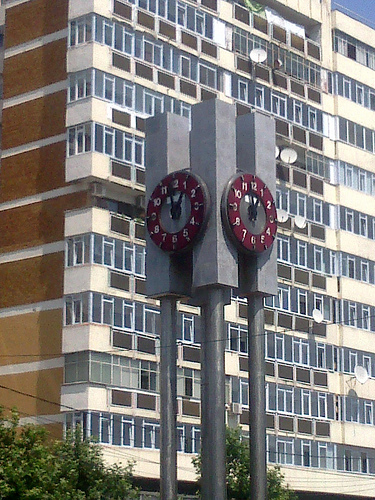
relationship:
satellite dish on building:
[242, 45, 275, 70] [1, 0, 373, 498]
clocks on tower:
[143, 162, 288, 260] [119, 94, 290, 489]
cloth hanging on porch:
[270, 26, 313, 41] [223, 13, 332, 66]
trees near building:
[0, 404, 299, 498] [1, 0, 373, 498]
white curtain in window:
[94, 237, 104, 260] [93, 231, 116, 261]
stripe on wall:
[10, 354, 63, 375] [108, 30, 225, 88]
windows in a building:
[63, 13, 328, 128] [1, 0, 373, 498]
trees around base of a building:
[2, 412, 136, 497] [1, 0, 373, 498]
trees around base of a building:
[196, 425, 291, 495] [1, 0, 373, 498]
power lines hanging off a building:
[1, 313, 373, 487] [1, 0, 373, 498]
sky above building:
[332, 2, 372, 25] [1, 0, 373, 498]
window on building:
[101, 236, 113, 266] [1, 0, 373, 498]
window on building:
[121, 244, 134, 271] [1, 0, 373, 498]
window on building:
[102, 126, 113, 155] [1, 0, 373, 498]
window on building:
[123, 133, 133, 163] [1, 0, 373, 498]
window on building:
[102, 73, 113, 98] [1, 0, 373, 498]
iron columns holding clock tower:
[160, 288, 265, 500] [105, 106, 290, 301]